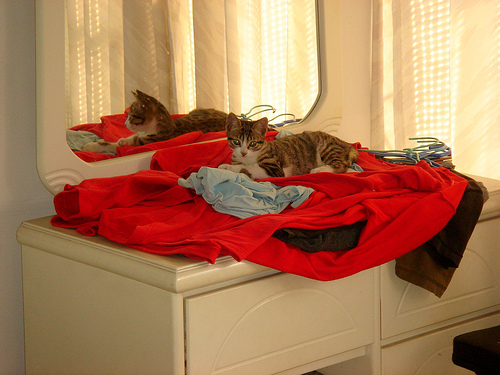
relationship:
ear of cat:
[225, 112, 238, 129] [222, 110, 364, 180]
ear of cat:
[250, 115, 269, 133] [222, 110, 364, 180]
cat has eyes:
[217, 111, 360, 180] [233, 137, 262, 148]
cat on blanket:
[217, 111, 360, 180] [55, 141, 467, 279]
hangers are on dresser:
[356, 132, 456, 167] [14, 173, 498, 373]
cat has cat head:
[222, 110, 364, 180] [225, 109, 265, 164]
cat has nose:
[222, 110, 364, 180] [238, 148, 248, 156]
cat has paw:
[217, 111, 360, 180] [110, 135, 140, 149]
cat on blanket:
[217, 111, 360, 180] [53, 123, 483, 272]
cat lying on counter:
[217, 111, 360, 180] [13, 151, 484, 292]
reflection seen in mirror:
[64, 0, 318, 163] [63, 1, 320, 162]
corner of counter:
[161, 260, 196, 297] [19, 206, 292, 313]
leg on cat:
[219, 157, 286, 182] [189, 113, 368, 175]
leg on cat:
[326, 154, 366, 177] [189, 113, 368, 175]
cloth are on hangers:
[176, 165, 317, 219] [360, 134, 458, 168]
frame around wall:
[31, 0, 373, 195] [1, 0, 30, 374]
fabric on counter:
[50, 129, 472, 280] [16, 165, 498, 374]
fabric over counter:
[163, 167, 493, 305] [187, 173, 445, 331]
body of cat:
[276, 127, 343, 175] [228, 119, 358, 180]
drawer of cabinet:
[173, 269, 387, 374] [20, 179, 496, 374]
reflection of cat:
[115, 95, 230, 138] [220, 112, 391, 174]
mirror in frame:
[40, 32, 350, 132] [16, 117, 96, 208]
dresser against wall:
[6, 205, 496, 374] [1, 2, 370, 372]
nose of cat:
[239, 149, 249, 155] [217, 111, 360, 180]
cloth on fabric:
[176, 165, 312, 219] [50, 129, 472, 280]